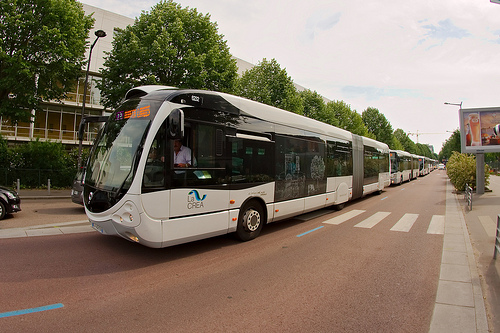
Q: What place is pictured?
A: It is a road.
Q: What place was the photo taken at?
A: It was taken at the road.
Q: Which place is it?
A: It is a road.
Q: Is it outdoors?
A: Yes, it is outdoors.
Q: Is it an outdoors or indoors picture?
A: It is outdoors.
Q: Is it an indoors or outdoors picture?
A: It is outdoors.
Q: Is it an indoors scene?
A: No, it is outdoors.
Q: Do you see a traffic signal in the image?
A: No, there are no traffic lights.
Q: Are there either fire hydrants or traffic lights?
A: No, there are no traffic lights or fire hydrants.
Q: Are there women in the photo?
A: No, there are no women.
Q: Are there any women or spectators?
A: No, there are no women or spectators.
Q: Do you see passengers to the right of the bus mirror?
A: Yes, there are passengers to the right of the mirror.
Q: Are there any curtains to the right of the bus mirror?
A: No, there are passengers to the right of the mirror.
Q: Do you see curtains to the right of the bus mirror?
A: No, there are passengers to the right of the mirror.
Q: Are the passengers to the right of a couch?
A: No, the passengers are to the right of a mirror.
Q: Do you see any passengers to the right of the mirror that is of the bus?
A: Yes, there are passengers to the right of the mirror.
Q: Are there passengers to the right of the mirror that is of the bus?
A: Yes, there are passengers to the right of the mirror.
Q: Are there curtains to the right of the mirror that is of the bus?
A: No, there are passengers to the right of the mirror.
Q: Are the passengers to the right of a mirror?
A: Yes, the passengers are to the right of a mirror.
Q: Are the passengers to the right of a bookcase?
A: No, the passengers are to the right of a mirror.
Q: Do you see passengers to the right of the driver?
A: Yes, there are passengers to the right of the driver.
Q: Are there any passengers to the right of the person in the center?
A: Yes, there are passengers to the right of the driver.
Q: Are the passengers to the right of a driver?
A: Yes, the passengers are to the right of a driver.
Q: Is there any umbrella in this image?
A: No, there are no umbrellas.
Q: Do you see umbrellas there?
A: No, there are no umbrellas.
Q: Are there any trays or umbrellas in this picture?
A: No, there are no umbrellas or trays.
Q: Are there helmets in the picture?
A: No, there are no helmets.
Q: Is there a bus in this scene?
A: Yes, there is a bus.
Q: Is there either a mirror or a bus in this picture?
A: Yes, there is a bus.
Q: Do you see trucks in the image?
A: No, there are no trucks.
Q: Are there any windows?
A: Yes, there are windows.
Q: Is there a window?
A: Yes, there are windows.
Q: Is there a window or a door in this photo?
A: Yes, there are windows.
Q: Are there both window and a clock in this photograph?
A: No, there are windows but no clocks.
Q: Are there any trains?
A: No, there are no trains.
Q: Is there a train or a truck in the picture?
A: No, there are no trains or trucks.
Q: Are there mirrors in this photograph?
A: Yes, there is a mirror.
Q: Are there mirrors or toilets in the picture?
A: Yes, there is a mirror.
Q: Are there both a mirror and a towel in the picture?
A: No, there is a mirror but no towels.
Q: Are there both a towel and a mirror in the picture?
A: No, there is a mirror but no towels.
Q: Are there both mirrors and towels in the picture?
A: No, there is a mirror but no towels.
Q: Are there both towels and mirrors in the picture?
A: No, there is a mirror but no towels.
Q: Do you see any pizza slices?
A: No, there are no pizza slices.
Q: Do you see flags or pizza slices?
A: No, there are no pizza slices or flags.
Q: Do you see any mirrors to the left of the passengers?
A: Yes, there is a mirror to the left of the passengers.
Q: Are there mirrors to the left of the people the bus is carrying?
A: Yes, there is a mirror to the left of the passengers.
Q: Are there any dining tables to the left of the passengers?
A: No, there is a mirror to the left of the passengers.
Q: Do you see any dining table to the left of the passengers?
A: No, there is a mirror to the left of the passengers.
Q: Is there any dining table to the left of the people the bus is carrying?
A: No, there is a mirror to the left of the passengers.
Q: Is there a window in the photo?
A: Yes, there are windows.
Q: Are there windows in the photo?
A: Yes, there are windows.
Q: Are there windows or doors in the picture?
A: Yes, there are windows.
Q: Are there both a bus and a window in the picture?
A: Yes, there are both a window and a bus.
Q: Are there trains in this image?
A: No, there are no trains.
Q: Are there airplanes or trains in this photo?
A: No, there are no trains or airplanes.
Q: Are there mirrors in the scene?
A: Yes, there is a mirror.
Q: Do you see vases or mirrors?
A: Yes, there is a mirror.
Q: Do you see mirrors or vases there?
A: Yes, there is a mirror.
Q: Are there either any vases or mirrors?
A: Yes, there is a mirror.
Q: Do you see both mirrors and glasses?
A: No, there is a mirror but no glasses.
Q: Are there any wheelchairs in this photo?
A: No, there are no wheelchairs.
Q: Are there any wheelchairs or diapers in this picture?
A: No, there are no wheelchairs or diapers.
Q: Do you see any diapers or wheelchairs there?
A: No, there are no wheelchairs or diapers.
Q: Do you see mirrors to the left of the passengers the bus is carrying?
A: Yes, there is a mirror to the left of the passengers.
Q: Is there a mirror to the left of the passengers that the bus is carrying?
A: Yes, there is a mirror to the left of the passengers.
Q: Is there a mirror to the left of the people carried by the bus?
A: Yes, there is a mirror to the left of the passengers.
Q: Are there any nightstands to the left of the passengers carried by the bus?
A: No, there is a mirror to the left of the passengers.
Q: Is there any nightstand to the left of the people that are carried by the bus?
A: No, there is a mirror to the left of the passengers.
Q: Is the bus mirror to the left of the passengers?
A: Yes, the mirror is to the left of the passengers.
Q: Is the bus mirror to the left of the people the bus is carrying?
A: Yes, the mirror is to the left of the passengers.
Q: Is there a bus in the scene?
A: Yes, there is a bus.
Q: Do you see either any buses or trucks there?
A: Yes, there is a bus.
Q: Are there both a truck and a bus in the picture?
A: No, there is a bus but no trucks.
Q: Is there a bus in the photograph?
A: Yes, there is a bus.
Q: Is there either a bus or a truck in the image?
A: Yes, there is a bus.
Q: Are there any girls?
A: No, there are no girls.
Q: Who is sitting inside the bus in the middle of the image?
A: The driver is sitting inside the bus.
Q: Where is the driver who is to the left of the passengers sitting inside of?
A: The driver is sitting inside the bus.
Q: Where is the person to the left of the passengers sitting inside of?
A: The driver is sitting inside the bus.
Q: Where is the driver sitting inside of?
A: The driver is sitting inside the bus.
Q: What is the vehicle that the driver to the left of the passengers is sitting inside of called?
A: The vehicle is a bus.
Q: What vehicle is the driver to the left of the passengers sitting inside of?
A: The driver is sitting inside the bus.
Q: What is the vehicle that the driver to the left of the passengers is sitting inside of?
A: The vehicle is a bus.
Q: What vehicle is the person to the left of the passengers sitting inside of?
A: The driver is sitting inside the bus.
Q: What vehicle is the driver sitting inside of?
A: The driver is sitting inside the bus.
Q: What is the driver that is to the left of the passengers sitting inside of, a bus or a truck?
A: The driver is sitting inside a bus.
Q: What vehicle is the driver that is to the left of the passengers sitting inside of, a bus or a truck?
A: The driver is sitting inside a bus.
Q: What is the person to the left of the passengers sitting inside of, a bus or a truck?
A: The driver is sitting inside a bus.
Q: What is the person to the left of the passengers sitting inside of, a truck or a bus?
A: The driver is sitting inside a bus.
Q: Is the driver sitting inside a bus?
A: Yes, the driver is sitting inside a bus.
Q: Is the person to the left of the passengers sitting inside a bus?
A: Yes, the driver is sitting inside a bus.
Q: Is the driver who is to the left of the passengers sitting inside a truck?
A: No, the driver is sitting inside a bus.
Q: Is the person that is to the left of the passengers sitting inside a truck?
A: No, the driver is sitting inside a bus.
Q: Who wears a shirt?
A: The driver wears a shirt.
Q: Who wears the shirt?
A: The driver wears a shirt.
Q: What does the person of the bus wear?
A: The driver wears a shirt.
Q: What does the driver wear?
A: The driver wears a shirt.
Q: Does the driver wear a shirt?
A: Yes, the driver wears a shirt.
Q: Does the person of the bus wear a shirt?
A: Yes, the driver wears a shirt.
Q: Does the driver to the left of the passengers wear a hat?
A: No, the driver wears a shirt.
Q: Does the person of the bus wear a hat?
A: No, the driver wears a shirt.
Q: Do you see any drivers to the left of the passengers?
A: Yes, there is a driver to the left of the passengers.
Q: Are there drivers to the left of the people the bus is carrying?
A: Yes, there is a driver to the left of the passengers.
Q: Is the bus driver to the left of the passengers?
A: Yes, the driver is to the left of the passengers.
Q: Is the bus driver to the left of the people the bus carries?
A: Yes, the driver is to the left of the passengers.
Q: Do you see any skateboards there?
A: No, there are no skateboards.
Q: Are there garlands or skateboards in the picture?
A: No, there are no skateboards or garlands.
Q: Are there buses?
A: Yes, there is a bus.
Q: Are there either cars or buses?
A: Yes, there is a bus.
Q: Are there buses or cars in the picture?
A: Yes, there is a bus.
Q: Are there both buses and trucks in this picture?
A: No, there is a bus but no trucks.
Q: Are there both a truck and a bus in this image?
A: No, there is a bus but no trucks.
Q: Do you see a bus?
A: Yes, there is a bus.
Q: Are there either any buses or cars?
A: Yes, there is a bus.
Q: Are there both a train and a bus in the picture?
A: No, there is a bus but no trains.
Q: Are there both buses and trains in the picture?
A: No, there is a bus but no trains.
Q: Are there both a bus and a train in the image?
A: No, there is a bus but no trains.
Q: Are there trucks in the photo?
A: No, there are no trucks.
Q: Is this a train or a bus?
A: This is a bus.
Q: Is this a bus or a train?
A: This is a bus.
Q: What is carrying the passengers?
A: The bus is carrying the passengers.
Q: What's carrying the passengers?
A: The bus is carrying the passengers.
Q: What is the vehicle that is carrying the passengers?
A: The vehicle is a bus.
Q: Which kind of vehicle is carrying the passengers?
A: The vehicle is a bus.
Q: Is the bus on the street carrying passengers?
A: Yes, the bus is carrying passengers.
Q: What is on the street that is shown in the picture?
A: The bus is on the street.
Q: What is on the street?
A: The bus is on the street.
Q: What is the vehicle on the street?
A: The vehicle is a bus.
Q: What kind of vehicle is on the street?
A: The vehicle is a bus.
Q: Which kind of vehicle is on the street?
A: The vehicle is a bus.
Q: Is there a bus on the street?
A: Yes, there is a bus on the street.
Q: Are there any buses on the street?
A: Yes, there is a bus on the street.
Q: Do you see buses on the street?
A: Yes, there is a bus on the street.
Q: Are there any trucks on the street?
A: No, there is a bus on the street.